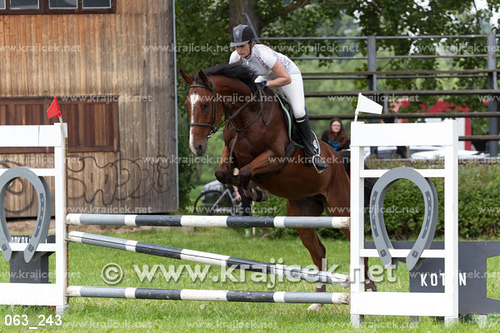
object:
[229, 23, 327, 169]
man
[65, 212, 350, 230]
pole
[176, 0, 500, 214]
tree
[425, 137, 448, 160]
ground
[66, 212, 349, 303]
barrier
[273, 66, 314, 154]
pants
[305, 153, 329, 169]
boot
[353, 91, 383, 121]
flag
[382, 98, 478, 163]
trailer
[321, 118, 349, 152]
woman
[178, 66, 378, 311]
horse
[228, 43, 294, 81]
shirt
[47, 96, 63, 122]
flag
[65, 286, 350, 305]
pole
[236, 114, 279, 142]
red wine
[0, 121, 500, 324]
barrier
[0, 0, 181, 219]
building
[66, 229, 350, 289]
pole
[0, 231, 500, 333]
grass